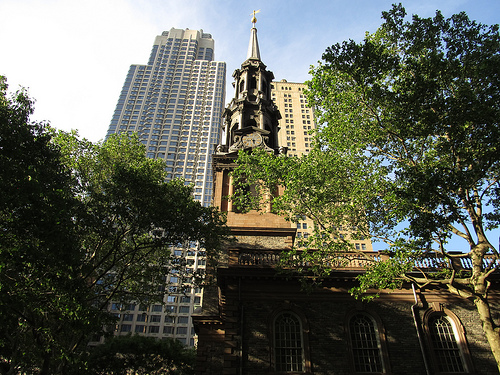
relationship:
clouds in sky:
[22, 14, 149, 105] [5, 4, 400, 56]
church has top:
[224, 239, 491, 370] [247, 11, 261, 61]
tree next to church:
[0, 73, 240, 375] [0, 190, 125, 375]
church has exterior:
[224, 239, 396, 369] [378, 290, 413, 305]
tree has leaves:
[229, 0, 500, 375] [324, 73, 394, 143]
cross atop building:
[248, 5, 261, 21] [194, 6, 498, 373]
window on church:
[348, 315, 386, 375] [224, 239, 491, 370]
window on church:
[426, 308, 468, 373] [224, 239, 491, 370]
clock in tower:
[233, 126, 266, 152] [214, 2, 299, 366]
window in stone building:
[274, 311, 303, 371] [243, 285, 446, 365]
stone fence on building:
[233, 246, 498, 272] [214, 245, 499, 374]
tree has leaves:
[229, 0, 500, 375] [324, 85, 381, 145]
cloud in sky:
[1, 0, 174, 145] [0, 1, 495, 257]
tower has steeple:
[213, 13, 294, 248] [235, 5, 270, 71]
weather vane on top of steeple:
[243, 6, 262, 60] [245, 28, 264, 55]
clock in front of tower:
[241, 130, 262, 147] [209, 9, 303, 250]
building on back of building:
[273, 78, 369, 254] [222, 250, 462, 373]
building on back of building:
[101, 20, 223, 343] [222, 250, 462, 373]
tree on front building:
[273, 31, 490, 351] [222, 250, 462, 373]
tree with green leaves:
[0, 73, 240, 371] [0, 76, 52, 359]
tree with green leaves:
[0, 73, 240, 371] [56, 130, 218, 250]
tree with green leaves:
[0, 73, 240, 371] [62, 255, 140, 350]